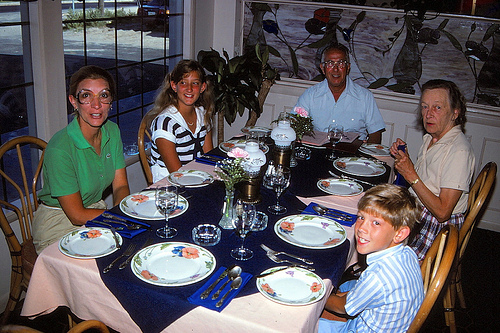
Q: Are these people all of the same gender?
A: No, they are both male and female.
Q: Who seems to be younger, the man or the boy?
A: The boy is younger than the man.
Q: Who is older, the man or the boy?
A: The man is older than the boy.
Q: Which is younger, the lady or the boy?
A: The boy is younger than the lady.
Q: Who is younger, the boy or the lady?
A: The boy is younger than the lady.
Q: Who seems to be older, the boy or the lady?
A: The lady is older than the boy.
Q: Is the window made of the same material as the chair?
A: No, the window is made of glass and the chair is made of wood.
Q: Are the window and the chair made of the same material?
A: No, the window is made of glass and the chair is made of wood.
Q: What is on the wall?
A: The drawing is on the wall.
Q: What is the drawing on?
A: The drawing is on the wall.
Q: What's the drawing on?
A: The drawing is on the wall.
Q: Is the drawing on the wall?
A: Yes, the drawing is on the wall.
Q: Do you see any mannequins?
A: No, there are no mannequins.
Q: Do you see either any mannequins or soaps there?
A: No, there are no mannequins or soaps.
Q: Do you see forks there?
A: Yes, there is a fork.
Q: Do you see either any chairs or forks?
A: Yes, there is a fork.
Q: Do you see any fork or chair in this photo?
A: Yes, there is a fork.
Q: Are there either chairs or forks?
A: Yes, there is a fork.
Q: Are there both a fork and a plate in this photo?
A: Yes, there are both a fork and a plate.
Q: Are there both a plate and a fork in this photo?
A: Yes, there are both a fork and a plate.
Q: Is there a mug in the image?
A: No, there are no mugs.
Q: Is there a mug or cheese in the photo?
A: No, there are no mugs or cheese.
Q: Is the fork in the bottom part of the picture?
A: Yes, the fork is in the bottom of the image.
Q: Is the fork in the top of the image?
A: No, the fork is in the bottom of the image.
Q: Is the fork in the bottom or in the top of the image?
A: The fork is in the bottom of the image.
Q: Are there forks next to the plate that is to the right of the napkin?
A: Yes, there is a fork next to the plate.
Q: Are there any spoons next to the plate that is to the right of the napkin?
A: No, there is a fork next to the plate.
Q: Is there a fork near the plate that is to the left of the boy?
A: Yes, there is a fork near the plate.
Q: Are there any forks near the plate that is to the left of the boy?
A: Yes, there is a fork near the plate.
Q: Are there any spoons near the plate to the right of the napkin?
A: No, there is a fork near the plate.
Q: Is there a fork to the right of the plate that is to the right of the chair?
A: Yes, there is a fork to the right of the plate.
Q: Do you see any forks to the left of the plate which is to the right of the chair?
A: No, the fork is to the right of the plate.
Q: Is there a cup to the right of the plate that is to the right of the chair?
A: No, there is a fork to the right of the plate.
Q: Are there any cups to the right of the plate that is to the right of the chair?
A: No, there is a fork to the right of the plate.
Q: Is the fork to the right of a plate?
A: Yes, the fork is to the right of a plate.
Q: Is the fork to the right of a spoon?
A: No, the fork is to the right of a plate.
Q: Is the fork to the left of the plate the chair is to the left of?
A: No, the fork is to the right of the plate.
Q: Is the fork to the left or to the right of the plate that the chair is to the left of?
A: The fork is to the right of the plate.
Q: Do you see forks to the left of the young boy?
A: Yes, there is a fork to the left of the boy.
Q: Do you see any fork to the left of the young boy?
A: Yes, there is a fork to the left of the boy.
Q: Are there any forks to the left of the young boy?
A: Yes, there is a fork to the left of the boy.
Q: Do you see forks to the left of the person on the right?
A: Yes, there is a fork to the left of the boy.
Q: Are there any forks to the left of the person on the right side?
A: Yes, there is a fork to the left of the boy.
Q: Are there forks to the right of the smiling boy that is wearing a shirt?
A: No, the fork is to the left of the boy.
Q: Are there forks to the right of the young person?
A: No, the fork is to the left of the boy.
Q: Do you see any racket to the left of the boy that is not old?
A: No, there is a fork to the left of the boy.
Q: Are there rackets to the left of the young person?
A: No, there is a fork to the left of the boy.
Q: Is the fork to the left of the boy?
A: Yes, the fork is to the left of the boy.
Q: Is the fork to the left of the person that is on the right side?
A: Yes, the fork is to the left of the boy.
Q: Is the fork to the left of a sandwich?
A: No, the fork is to the left of the boy.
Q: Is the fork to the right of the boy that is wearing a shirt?
A: No, the fork is to the left of the boy.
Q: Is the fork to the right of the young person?
A: No, the fork is to the left of the boy.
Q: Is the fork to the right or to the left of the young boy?
A: The fork is to the left of the boy.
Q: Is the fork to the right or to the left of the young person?
A: The fork is to the left of the boy.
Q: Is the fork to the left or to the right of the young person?
A: The fork is to the left of the boy.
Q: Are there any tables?
A: Yes, there is a table.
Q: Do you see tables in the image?
A: Yes, there is a table.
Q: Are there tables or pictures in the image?
A: Yes, there is a table.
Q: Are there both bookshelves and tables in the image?
A: No, there is a table but no bookshelves.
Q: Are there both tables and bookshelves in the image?
A: No, there is a table but no bookshelves.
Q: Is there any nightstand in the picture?
A: No, there are no nightstands.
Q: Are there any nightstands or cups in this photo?
A: No, there are no nightstands or cups.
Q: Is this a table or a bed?
A: This is a table.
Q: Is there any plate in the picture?
A: Yes, there is a plate.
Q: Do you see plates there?
A: Yes, there is a plate.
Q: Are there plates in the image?
A: Yes, there is a plate.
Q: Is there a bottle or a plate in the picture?
A: Yes, there is a plate.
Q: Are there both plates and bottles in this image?
A: No, there is a plate but no bottles.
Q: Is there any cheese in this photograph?
A: No, there is no cheese.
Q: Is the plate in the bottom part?
A: Yes, the plate is in the bottom of the image.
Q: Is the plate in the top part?
A: No, the plate is in the bottom of the image.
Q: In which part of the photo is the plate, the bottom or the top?
A: The plate is in the bottom of the image.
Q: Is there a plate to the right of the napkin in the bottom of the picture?
A: Yes, there is a plate to the right of the napkin.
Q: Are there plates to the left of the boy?
A: Yes, there is a plate to the left of the boy.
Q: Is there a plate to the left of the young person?
A: Yes, there is a plate to the left of the boy.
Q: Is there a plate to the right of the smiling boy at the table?
A: No, the plate is to the left of the boy.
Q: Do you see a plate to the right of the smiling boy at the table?
A: No, the plate is to the left of the boy.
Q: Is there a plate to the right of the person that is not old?
A: No, the plate is to the left of the boy.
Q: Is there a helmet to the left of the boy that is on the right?
A: No, there is a plate to the left of the boy.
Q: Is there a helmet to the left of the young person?
A: No, there is a plate to the left of the boy.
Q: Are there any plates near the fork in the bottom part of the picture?
A: Yes, there is a plate near the fork.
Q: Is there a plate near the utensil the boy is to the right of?
A: Yes, there is a plate near the fork.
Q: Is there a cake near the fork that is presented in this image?
A: No, there is a plate near the fork.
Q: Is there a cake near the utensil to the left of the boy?
A: No, there is a plate near the fork.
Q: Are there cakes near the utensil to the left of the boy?
A: No, there is a plate near the fork.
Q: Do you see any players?
A: No, there are no players.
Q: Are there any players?
A: No, there are no players.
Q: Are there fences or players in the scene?
A: No, there are no players or fences.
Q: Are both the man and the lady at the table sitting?
A: Yes, both the man and the lady are sitting.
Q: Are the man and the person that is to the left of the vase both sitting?
A: Yes, both the man and the lady are sitting.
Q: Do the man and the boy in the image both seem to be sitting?
A: Yes, both the man and the boy are sitting.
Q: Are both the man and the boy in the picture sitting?
A: Yes, both the man and the boy are sitting.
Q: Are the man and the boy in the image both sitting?
A: Yes, both the man and the boy are sitting.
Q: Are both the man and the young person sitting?
A: Yes, both the man and the boy are sitting.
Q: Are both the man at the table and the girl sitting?
A: Yes, both the man and the girl are sitting.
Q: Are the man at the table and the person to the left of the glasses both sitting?
A: Yes, both the man and the girl are sitting.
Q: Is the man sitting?
A: Yes, the man is sitting.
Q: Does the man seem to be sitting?
A: Yes, the man is sitting.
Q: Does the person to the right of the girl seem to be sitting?
A: Yes, the man is sitting.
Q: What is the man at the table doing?
A: The man is sitting.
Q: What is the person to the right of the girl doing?
A: The man is sitting.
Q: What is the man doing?
A: The man is sitting.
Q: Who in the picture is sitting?
A: The man is sitting.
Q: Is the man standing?
A: No, the man is sitting.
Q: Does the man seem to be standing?
A: No, the man is sitting.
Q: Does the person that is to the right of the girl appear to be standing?
A: No, the man is sitting.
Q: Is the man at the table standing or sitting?
A: The man is sitting.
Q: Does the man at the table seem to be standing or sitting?
A: The man is sitting.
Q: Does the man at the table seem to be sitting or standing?
A: The man is sitting.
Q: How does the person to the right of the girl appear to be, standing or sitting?
A: The man is sitting.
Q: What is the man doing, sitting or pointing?
A: The man is sitting.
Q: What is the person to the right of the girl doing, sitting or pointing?
A: The man is sitting.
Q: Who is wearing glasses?
A: The man is wearing glasses.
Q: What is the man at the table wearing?
A: The man is wearing glasses.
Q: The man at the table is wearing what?
A: The man is wearing glasses.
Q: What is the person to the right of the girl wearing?
A: The man is wearing glasses.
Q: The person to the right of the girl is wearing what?
A: The man is wearing glasses.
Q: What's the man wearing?
A: The man is wearing glasses.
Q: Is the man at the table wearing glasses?
A: Yes, the man is wearing glasses.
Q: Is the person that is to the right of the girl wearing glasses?
A: Yes, the man is wearing glasses.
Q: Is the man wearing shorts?
A: No, the man is wearing glasses.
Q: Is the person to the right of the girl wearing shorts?
A: No, the man is wearing glasses.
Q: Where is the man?
A: The man is at the table.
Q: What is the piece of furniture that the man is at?
A: The piece of furniture is a table.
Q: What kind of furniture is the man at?
A: The man is at the table.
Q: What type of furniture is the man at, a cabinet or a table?
A: The man is at a table.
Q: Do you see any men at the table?
A: Yes, there is a man at the table.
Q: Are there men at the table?
A: Yes, there is a man at the table.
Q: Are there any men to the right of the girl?
A: Yes, there is a man to the right of the girl.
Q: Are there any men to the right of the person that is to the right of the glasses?
A: Yes, there is a man to the right of the girl.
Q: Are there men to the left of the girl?
A: No, the man is to the right of the girl.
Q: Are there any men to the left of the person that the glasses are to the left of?
A: No, the man is to the right of the girl.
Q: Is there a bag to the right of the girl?
A: No, there is a man to the right of the girl.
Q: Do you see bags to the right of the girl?
A: No, there is a man to the right of the girl.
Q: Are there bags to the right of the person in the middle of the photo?
A: No, there is a man to the right of the girl.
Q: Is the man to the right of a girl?
A: Yes, the man is to the right of a girl.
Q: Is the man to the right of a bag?
A: No, the man is to the right of a girl.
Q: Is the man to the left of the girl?
A: No, the man is to the right of the girl.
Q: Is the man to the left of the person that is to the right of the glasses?
A: No, the man is to the right of the girl.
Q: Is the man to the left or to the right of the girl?
A: The man is to the right of the girl.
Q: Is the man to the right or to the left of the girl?
A: The man is to the right of the girl.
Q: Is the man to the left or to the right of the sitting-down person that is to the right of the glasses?
A: The man is to the right of the girl.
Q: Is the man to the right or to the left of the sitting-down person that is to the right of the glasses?
A: The man is to the right of the girl.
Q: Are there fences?
A: No, there are no fences.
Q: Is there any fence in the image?
A: No, there are no fences.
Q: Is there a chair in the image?
A: Yes, there is a chair.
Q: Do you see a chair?
A: Yes, there is a chair.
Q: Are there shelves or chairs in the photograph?
A: Yes, there is a chair.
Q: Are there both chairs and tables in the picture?
A: Yes, there are both a chair and a table.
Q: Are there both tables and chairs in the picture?
A: Yes, there are both a chair and a table.